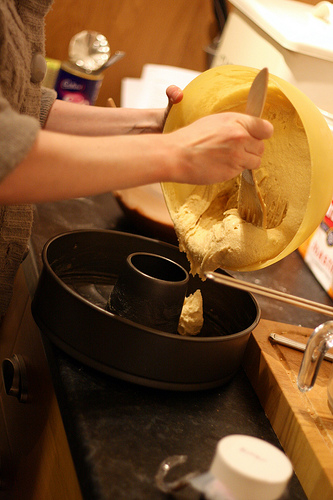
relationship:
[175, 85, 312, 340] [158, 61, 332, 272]
cake mixture in a mixing bowl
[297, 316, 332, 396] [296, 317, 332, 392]
handle of a handle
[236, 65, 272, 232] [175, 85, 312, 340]
spatula scraping cake mixture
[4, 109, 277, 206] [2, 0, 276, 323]
arm held out in front person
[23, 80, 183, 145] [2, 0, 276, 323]
arm held out in front person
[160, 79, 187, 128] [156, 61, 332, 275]
left hand grips mixing bowl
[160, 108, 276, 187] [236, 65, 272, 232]
right hand holds a spatula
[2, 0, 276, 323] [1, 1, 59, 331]
person wearing a sweater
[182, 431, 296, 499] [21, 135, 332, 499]
measuring cup on counter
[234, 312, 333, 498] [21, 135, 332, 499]
chopping board on counter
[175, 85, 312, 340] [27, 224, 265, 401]
cake mixture in cake tin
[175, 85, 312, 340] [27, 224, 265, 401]
cake mixture being scraped to cake tin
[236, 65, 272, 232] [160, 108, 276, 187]
spatula in right hand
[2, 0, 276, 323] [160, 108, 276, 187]
person has right hand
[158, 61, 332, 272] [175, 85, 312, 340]
mixing bowl full of cake mixture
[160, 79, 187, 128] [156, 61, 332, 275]
left hand gripping a mixing bowl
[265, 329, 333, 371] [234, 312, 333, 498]
knife resting on a chopping board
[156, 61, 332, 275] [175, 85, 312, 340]
mixing bowl of cake mixture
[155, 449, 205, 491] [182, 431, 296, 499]
handle of a measuring cup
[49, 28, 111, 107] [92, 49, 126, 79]
frosting container with a spoon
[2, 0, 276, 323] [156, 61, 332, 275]
person holding mixing bowl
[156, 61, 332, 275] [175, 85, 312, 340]
mixing bowl has cake mixture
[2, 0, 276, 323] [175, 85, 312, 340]
person pouring cake mixture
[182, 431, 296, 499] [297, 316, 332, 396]
measuring cup has handle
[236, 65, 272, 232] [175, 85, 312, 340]
spatula used to mix cake mixture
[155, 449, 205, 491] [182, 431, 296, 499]
handle of measuring cup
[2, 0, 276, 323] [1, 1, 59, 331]
person wearing sweater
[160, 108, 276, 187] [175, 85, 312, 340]
right hand scooping cake mixture